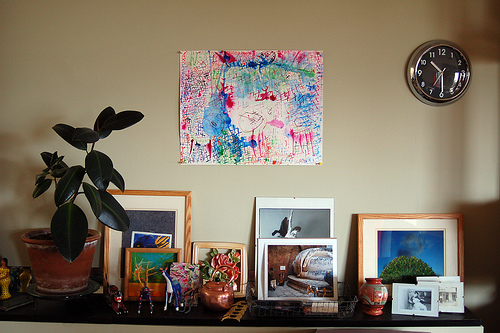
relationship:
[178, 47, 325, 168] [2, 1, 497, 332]
drawing on wall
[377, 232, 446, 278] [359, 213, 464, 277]
photograph in frame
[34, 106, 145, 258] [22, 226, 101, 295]
plant in pot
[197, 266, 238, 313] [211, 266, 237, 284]
tea pot has handle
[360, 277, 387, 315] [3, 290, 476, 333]
vase on table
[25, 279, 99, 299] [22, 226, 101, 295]
dish under pot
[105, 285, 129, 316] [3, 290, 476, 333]
animal on table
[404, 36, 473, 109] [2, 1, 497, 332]
clock on wall